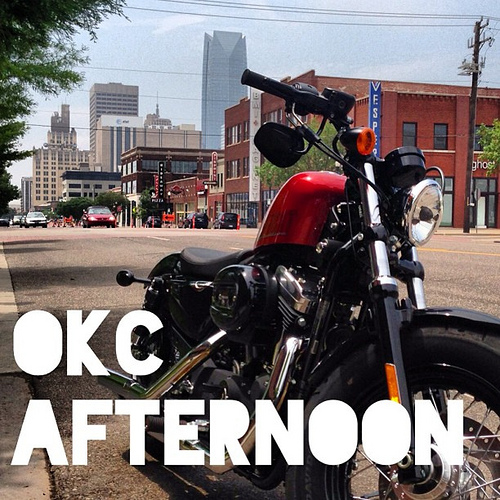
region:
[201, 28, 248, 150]
tall building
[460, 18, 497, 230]
wooden electrical pole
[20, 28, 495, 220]
multiple buildings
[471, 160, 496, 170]
store name on the building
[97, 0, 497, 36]
electrical lines in the air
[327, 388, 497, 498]
chrome spokes on the tire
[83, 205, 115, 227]
small red car on the street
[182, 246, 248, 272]
black leather seat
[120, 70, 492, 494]
motorcycle is parked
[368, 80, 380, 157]
tall blue and white sign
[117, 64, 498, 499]
a red motorcycle parked on street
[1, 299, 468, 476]
a short word phrase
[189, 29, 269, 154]
a tall skyscraper building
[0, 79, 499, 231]
the central part of the city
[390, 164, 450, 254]
the motorcycle head lamp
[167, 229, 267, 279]
motorcycle back seat pad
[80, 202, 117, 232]
a red sedan car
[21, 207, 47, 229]
a gray sedan car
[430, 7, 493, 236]
a power line post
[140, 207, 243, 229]
cars parked on the street meter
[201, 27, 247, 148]
tall building is glass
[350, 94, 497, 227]
red brick building on corner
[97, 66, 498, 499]
motorcycle is parked on side of road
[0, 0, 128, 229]
tree overhanging the road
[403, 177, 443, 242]
headlight on parked motorcycle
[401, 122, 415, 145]
window on brick building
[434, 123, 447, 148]
window on brick building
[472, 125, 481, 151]
window on brick building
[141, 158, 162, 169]
window on brick building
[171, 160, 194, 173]
window on brick building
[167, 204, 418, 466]
A motorbike in the photo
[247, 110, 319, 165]
Side mirror in the photo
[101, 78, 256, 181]
Buildings in the photo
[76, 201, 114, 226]
A red car in the photo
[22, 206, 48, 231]
A gray car in the photo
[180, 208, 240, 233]
Black cars in the photo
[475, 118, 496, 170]
Leaves of a tree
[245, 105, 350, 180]
A tree at the back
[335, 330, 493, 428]
Bike tire in the photo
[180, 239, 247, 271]
Seat of a motorbike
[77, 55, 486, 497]
bike parked on the street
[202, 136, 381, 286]
the bike is red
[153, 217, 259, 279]
the seat is black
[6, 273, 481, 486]
the letters are white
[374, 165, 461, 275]
the headlight is on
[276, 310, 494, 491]
the wheel is black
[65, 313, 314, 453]
the pipes are silver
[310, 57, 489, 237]
the building is reddish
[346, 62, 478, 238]
the building is made of bricks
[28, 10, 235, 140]
the sky is overcast